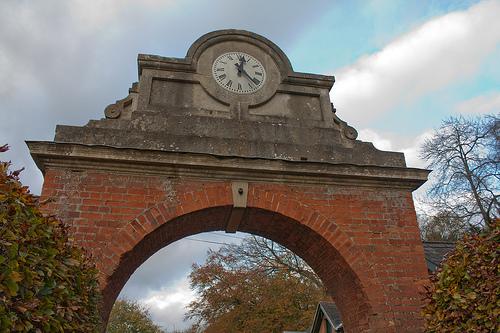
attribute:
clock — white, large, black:
[211, 51, 267, 94]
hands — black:
[234, 56, 259, 86]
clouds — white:
[323, 1, 498, 224]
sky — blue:
[1, 0, 499, 332]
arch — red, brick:
[39, 168, 433, 333]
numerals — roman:
[217, 55, 262, 90]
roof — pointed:
[305, 302, 342, 333]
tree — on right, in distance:
[414, 112, 498, 242]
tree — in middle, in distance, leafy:
[182, 228, 333, 332]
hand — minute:
[234, 63, 259, 86]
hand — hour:
[236, 55, 245, 78]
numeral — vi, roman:
[236, 82, 242, 92]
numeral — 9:
[216, 66, 226, 73]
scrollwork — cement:
[103, 81, 140, 120]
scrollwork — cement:
[330, 104, 362, 143]